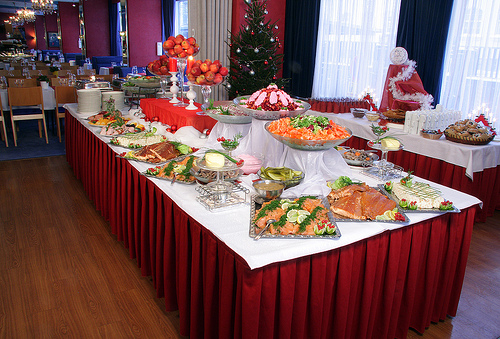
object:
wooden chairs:
[3, 77, 88, 153]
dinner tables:
[0, 73, 79, 135]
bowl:
[189, 76, 227, 114]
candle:
[184, 56, 196, 107]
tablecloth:
[63, 98, 482, 339]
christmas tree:
[219, 0, 290, 99]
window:
[312, 1, 402, 111]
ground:
[468, 102, 477, 109]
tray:
[248, 179, 340, 239]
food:
[89, 50, 461, 238]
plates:
[75, 87, 103, 116]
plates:
[100, 89, 128, 109]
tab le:
[57, 91, 454, 333]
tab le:
[318, 105, 500, 186]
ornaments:
[253, 48, 257, 52]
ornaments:
[236, 48, 239, 53]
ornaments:
[251, 31, 253, 36]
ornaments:
[263, 60, 267, 64]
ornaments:
[273, 74, 277, 79]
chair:
[54, 79, 79, 139]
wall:
[261, 81, 368, 108]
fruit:
[187, 54, 228, 86]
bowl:
[265, 123, 353, 151]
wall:
[230, 1, 285, 93]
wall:
[127, 1, 163, 65]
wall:
[81, 0, 112, 57]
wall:
[56, 3, 84, 54]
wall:
[44, 13, 58, 50]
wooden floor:
[0, 152, 498, 336]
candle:
[167, 56, 178, 71]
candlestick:
[166, 70, 179, 102]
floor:
[3, 137, 499, 337]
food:
[254, 195, 336, 234]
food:
[325, 175, 407, 222]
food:
[382, 172, 457, 210]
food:
[118, 140, 199, 162]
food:
[265, 114, 353, 149]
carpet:
[60, 106, 477, 337]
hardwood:
[2, 112, 67, 155]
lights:
[1, 6, 19, 25]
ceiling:
[2, 0, 26, 6]